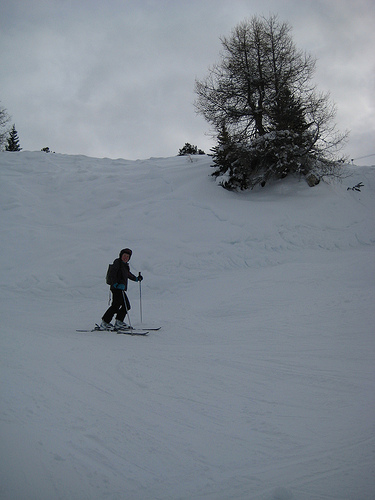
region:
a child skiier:
[82, 246, 166, 345]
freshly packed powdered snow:
[17, 353, 350, 475]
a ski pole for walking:
[133, 268, 149, 331]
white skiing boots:
[93, 311, 133, 336]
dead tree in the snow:
[194, 4, 346, 202]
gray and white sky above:
[17, 48, 170, 132]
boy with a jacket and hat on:
[103, 241, 138, 295]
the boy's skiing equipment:
[75, 325, 166, 335]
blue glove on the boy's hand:
[108, 278, 129, 294]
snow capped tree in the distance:
[162, 131, 208, 162]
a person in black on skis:
[85, 230, 166, 341]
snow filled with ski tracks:
[92, 350, 323, 475]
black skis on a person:
[78, 316, 172, 346]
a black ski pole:
[136, 268, 151, 330]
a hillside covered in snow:
[35, 142, 199, 255]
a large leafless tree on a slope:
[188, 21, 355, 185]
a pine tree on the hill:
[4, 125, 21, 158]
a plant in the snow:
[342, 179, 364, 195]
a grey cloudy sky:
[36, 16, 161, 111]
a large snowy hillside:
[35, 104, 373, 249]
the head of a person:
[115, 243, 134, 265]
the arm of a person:
[125, 266, 137, 283]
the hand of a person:
[134, 272, 146, 284]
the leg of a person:
[101, 289, 122, 321]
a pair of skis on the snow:
[75, 318, 165, 338]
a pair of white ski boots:
[96, 316, 134, 332]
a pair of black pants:
[99, 287, 133, 322]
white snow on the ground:
[1, 148, 373, 498]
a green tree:
[4, 121, 25, 154]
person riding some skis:
[73, 234, 168, 354]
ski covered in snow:
[63, 321, 159, 339]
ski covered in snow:
[118, 318, 166, 331]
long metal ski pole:
[136, 264, 144, 325]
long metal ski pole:
[116, 278, 143, 336]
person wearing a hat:
[79, 232, 157, 345]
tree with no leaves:
[179, 15, 346, 201]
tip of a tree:
[171, 136, 210, 163]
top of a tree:
[3, 123, 28, 155]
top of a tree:
[39, 146, 64, 160]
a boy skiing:
[80, 222, 174, 363]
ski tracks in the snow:
[216, 431, 325, 491]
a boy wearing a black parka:
[90, 230, 162, 346]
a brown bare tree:
[212, 23, 310, 134]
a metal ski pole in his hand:
[138, 282, 150, 317]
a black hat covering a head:
[123, 250, 135, 254]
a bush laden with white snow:
[228, 136, 310, 192]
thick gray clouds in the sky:
[67, 47, 164, 122]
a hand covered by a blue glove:
[113, 280, 125, 288]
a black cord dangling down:
[105, 290, 111, 303]